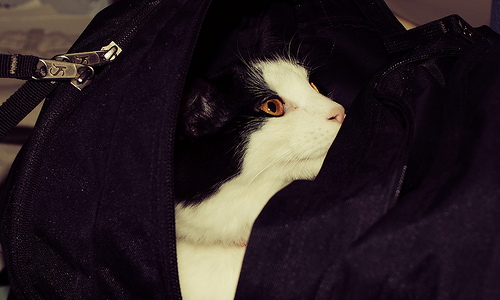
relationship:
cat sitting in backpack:
[171, 41, 346, 299] [0, 0, 499, 300]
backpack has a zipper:
[0, 0, 499, 300] [0, 1, 164, 298]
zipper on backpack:
[0, 1, 164, 298] [0, 0, 499, 300]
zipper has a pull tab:
[0, 1, 164, 298] [55, 39, 124, 72]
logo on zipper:
[48, 60, 69, 77] [0, 1, 164, 298]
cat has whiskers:
[171, 41, 346, 299] [234, 138, 326, 182]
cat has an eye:
[171, 41, 346, 299] [252, 94, 286, 118]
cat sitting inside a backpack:
[171, 41, 346, 299] [0, 0, 499, 300]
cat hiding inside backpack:
[171, 41, 346, 299] [0, 0, 499, 300]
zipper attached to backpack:
[0, 1, 164, 298] [0, 0, 499, 300]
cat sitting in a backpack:
[171, 41, 346, 299] [0, 0, 499, 300]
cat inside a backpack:
[171, 41, 346, 299] [0, 0, 499, 300]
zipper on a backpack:
[0, 1, 164, 298] [0, 0, 499, 300]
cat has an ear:
[171, 41, 346, 299] [185, 83, 232, 134]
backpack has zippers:
[0, 0, 499, 300] [5, 3, 165, 295]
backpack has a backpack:
[3, 3, 498, 299] [0, 0, 499, 300]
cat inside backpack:
[171, 41, 346, 299] [3, 3, 498, 299]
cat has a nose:
[171, 41, 346, 299] [326, 104, 345, 123]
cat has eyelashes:
[171, 41, 346, 299] [232, 34, 320, 87]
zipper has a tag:
[0, 1, 164, 298] [31, 54, 98, 92]